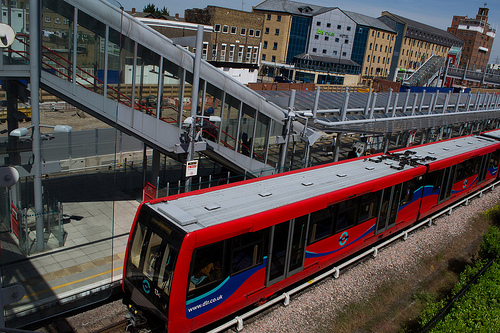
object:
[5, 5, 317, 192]
stairs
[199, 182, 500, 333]
rail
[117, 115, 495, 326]
subway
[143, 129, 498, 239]
top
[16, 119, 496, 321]
paved platform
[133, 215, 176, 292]
window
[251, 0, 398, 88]
building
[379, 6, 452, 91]
building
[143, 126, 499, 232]
roof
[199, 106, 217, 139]
people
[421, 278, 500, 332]
foilage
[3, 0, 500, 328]
depot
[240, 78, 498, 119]
train platform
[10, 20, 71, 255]
lamp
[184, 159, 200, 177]
sign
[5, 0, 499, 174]
structure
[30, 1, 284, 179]
staircase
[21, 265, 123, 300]
line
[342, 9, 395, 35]
roof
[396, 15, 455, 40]
roof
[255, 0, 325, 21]
roof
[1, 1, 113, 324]
glass wall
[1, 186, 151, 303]
platform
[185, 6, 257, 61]
brown building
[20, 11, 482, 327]
station